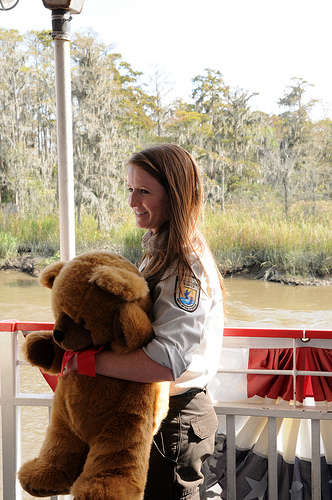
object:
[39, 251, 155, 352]
head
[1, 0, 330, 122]
sky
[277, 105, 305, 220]
trees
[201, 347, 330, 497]
flag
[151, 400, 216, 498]
pants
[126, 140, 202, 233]
head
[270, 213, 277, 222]
grass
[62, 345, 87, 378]
woman's hands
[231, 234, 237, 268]
grass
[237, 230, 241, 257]
grass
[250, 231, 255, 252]
grass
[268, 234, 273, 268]
grass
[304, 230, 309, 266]
grass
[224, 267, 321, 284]
shore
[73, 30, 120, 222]
trees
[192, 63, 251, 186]
trees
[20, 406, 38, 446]
water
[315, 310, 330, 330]
water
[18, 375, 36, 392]
water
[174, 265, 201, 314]
logo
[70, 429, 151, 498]
leg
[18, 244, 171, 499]
bear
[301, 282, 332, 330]
river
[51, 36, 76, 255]
white pole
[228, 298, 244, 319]
water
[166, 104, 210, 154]
trees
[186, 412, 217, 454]
pocket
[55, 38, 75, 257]
lampstand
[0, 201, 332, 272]
grassy area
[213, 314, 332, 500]
railing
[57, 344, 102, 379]
bowtie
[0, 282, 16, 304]
water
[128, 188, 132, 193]
eye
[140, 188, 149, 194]
eye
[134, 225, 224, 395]
shirt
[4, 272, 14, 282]
water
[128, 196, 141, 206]
nose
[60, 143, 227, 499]
lady